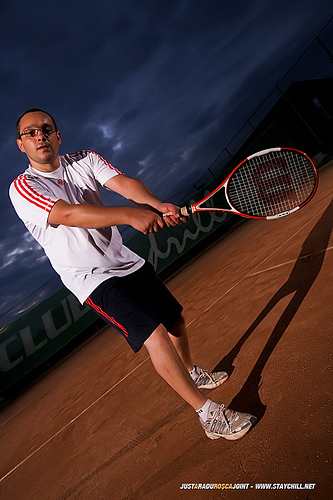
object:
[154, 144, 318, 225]
racket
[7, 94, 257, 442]
man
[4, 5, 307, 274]
sky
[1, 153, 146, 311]
shirt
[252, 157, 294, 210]
logo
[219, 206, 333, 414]
shadow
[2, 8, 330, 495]
day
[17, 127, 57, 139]
eyeglasses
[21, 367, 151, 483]
dirt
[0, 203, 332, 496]
tennis court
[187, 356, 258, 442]
shoes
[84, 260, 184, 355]
shorts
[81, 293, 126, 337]
stripes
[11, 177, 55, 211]
stripes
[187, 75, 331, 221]
fence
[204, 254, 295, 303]
stripe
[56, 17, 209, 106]
skies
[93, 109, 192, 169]
clouds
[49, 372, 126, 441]
line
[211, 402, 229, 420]
lines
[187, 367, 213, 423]
socks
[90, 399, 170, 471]
marks